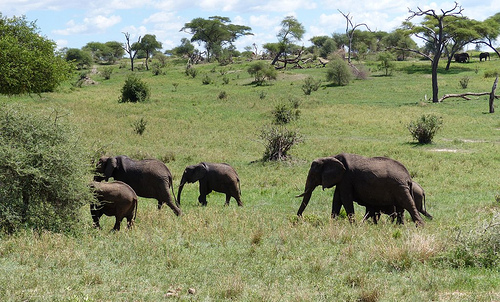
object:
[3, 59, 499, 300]
grass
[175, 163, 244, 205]
baby elephant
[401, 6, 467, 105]
tree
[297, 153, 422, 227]
elephant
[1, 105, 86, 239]
bush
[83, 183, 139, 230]
elephants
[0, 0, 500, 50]
sky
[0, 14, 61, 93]
bush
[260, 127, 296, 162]
bush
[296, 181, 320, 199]
tusk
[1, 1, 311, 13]
clouds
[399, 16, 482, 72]
trees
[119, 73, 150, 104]
bush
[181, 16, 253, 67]
tree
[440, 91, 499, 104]
branch